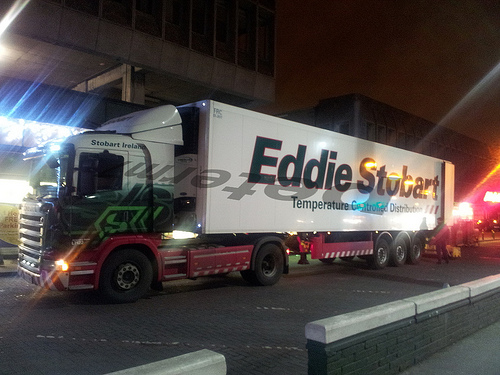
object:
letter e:
[246, 135, 282, 185]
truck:
[17, 97, 454, 305]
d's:
[276, 146, 305, 188]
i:
[325, 150, 339, 191]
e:
[333, 162, 353, 190]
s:
[356, 155, 381, 194]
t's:
[373, 165, 385, 196]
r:
[423, 177, 433, 199]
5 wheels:
[97, 249, 156, 304]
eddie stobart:
[249, 134, 438, 201]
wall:
[322, 320, 432, 356]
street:
[128, 295, 293, 348]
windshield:
[29, 145, 73, 195]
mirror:
[93, 153, 122, 178]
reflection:
[60, 153, 400, 215]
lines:
[404, 297, 423, 327]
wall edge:
[305, 263, 500, 327]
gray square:
[421, 205, 429, 215]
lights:
[452, 201, 474, 221]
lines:
[15, 331, 326, 352]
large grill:
[17, 212, 41, 275]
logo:
[95, 205, 165, 241]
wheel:
[410, 235, 424, 263]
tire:
[96, 248, 153, 303]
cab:
[16, 130, 172, 304]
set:
[368, 230, 427, 269]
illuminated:
[53, 259, 70, 273]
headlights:
[37, 199, 55, 216]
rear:
[403, 153, 455, 264]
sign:
[1, 205, 27, 258]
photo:
[0, 1, 497, 373]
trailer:
[180, 99, 455, 231]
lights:
[49, 258, 74, 274]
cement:
[303, 297, 416, 346]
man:
[427, 217, 452, 265]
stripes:
[322, 248, 376, 257]